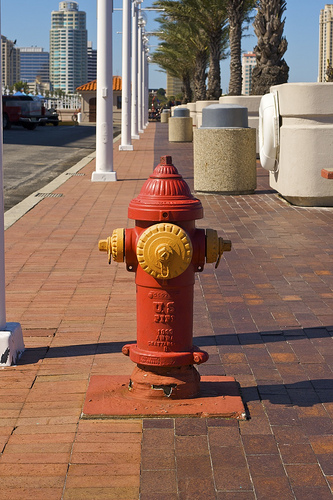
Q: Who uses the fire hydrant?
A: Firemen.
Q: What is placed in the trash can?
A: Trash.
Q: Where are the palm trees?
A: Along the street.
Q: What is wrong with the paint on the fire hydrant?
A: It's old.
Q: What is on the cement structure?
A: Life preserver.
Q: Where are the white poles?
A: Sidewalk.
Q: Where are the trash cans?
A: Sidewalk.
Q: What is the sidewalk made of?
A: Bricks.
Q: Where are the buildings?
A: In the distance.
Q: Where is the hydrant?
A: On the sidewalk.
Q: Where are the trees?
A: Next to the sidewalk.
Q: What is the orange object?
A: Hydrant.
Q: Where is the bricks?
A: On the sidewalk.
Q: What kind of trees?
A: Palm.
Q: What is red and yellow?
A: Fire hydrant.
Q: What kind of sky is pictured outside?
A: A clear blue sky.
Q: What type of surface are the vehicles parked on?
A: A gray asphalt road.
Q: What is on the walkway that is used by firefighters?
A: Red and yellow fire hydrant.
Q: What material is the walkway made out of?
A: Red brick.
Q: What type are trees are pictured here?
A: Palm trees.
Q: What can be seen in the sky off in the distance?
A: Tall buildings.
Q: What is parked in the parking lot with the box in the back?
A: A red truck.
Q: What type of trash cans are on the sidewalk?
A: Cement.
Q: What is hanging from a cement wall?
A: Life preserver.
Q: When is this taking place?
A: Daytime.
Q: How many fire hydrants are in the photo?
A: One.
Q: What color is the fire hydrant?
A: Red and orange.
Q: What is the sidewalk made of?
A: Brick.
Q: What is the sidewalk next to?
A: Street.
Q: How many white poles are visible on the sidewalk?
A: Five.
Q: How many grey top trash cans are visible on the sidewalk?
A: Three.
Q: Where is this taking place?
A: On a city sidewalk.